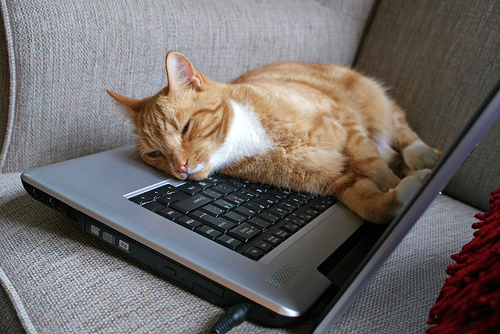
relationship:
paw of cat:
[402, 141, 443, 172] [106, 50, 442, 225]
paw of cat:
[392, 164, 434, 205] [106, 50, 442, 225]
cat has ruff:
[47, 42, 493, 231] [201, 82, 309, 182]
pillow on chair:
[0, 0, 367, 168] [1, 3, 472, 333]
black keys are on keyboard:
[128, 174, 335, 258] [113, 154, 340, 264]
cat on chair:
[106, 50, 442, 225] [0, 0, 499, 334]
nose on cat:
[174, 162, 187, 173] [106, 50, 442, 225]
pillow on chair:
[428, 205, 494, 309] [0, 0, 499, 334]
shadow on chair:
[0, 184, 100, 247] [0, 0, 499, 334]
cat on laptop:
[106, 50, 442, 225] [18, 83, 497, 328]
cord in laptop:
[203, 294, 258, 331] [18, 83, 497, 328]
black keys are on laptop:
[169, 193, 211, 214] [18, 83, 497, 328]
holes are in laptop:
[20, 177, 64, 211] [51, 71, 469, 313]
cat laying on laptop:
[106, 50, 442, 225] [18, 83, 497, 328]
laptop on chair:
[18, 83, 497, 328] [0, 0, 499, 334]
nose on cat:
[169, 160, 196, 177] [106, 50, 442, 225]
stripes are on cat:
[333, 105, 375, 155] [120, 77, 303, 215]